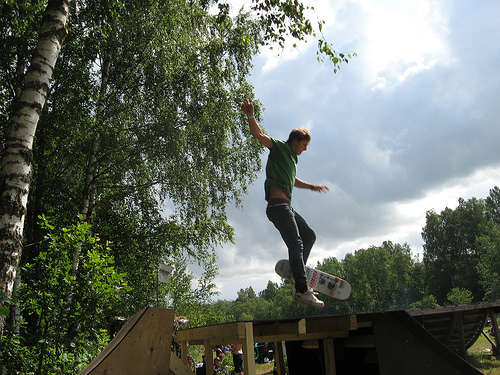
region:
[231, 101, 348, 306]
The guy is skateboarding.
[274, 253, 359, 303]
The skateboard has stickers on it.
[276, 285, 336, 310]
The shoes are white.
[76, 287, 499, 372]
He is doing tricks on a ramp.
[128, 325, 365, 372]
The ramp is made of wood.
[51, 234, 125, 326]
The tree leaves are green.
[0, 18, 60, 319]
Moss growing on the tree.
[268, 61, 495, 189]
A lot of clouds in the sky.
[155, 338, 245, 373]
People are watching the skateboarder.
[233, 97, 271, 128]
He is wearing a watch.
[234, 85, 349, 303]
a man skating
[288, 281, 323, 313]
a white shoe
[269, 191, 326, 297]
a pair of trousers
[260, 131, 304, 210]
a green shirt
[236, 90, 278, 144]
a stretched out arm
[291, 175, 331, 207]
a stretched out arm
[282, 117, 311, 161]
a man's head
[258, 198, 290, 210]
a man's belt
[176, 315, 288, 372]
people gathered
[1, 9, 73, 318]
a large tree trunk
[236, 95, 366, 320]
skateboarder in the air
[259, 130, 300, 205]
short sleeved green tee shirt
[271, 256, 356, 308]
bottom of white skateboard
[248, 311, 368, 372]
wood frame of ramp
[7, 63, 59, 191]
white trunk of birch tree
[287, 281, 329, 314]
white sneaker on skateboarder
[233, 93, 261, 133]
man's wrist with watch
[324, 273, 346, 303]
yellow wheels on skateboard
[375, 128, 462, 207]
dark clouds in sky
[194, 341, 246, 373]
people sitting on grass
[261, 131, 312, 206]
HIS SHIRT IS GREEN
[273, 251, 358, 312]
HE IS WEARING SNEAKERS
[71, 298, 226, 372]
THE RAMP IS MADE OF WOOD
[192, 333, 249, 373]
PEOPLE ARE IN THE BACKGROUND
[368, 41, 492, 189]
THE SKY IS CLOUDY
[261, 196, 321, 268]
HE IS WEARING JEANS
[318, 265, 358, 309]
HIS SKATEBOARD HAS YELLOW WHEELS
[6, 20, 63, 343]
A BIG TREE IS NEARBY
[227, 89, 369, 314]
HE IS IN THE AIR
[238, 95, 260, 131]
THE WATCH IS SILVER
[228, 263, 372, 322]
White skate board in the air.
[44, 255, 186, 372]
Wooden skate board ramp.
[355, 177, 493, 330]
Tall green trees and leaves.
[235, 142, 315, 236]
A persons green shirt.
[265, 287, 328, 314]
One white sport shoe.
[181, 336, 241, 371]
People spectating a skateboarder.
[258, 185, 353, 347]
A pair of gray pants.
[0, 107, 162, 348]
Tree with black and white trunk.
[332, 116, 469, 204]
Gray sky and white clouds.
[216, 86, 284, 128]
Watch on a persons wrist.